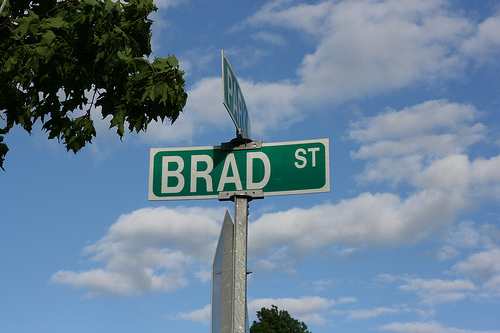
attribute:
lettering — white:
[160, 147, 319, 194]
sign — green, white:
[147, 138, 332, 200]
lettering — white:
[226, 66, 248, 134]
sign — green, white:
[221, 49, 253, 141]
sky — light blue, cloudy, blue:
[1, 1, 499, 331]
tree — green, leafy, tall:
[0, 1, 189, 171]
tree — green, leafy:
[249, 304, 310, 332]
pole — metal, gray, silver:
[229, 194, 253, 332]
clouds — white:
[17, 0, 499, 331]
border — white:
[148, 137, 332, 202]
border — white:
[220, 46, 248, 141]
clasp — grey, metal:
[216, 187, 265, 201]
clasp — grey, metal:
[222, 141, 264, 153]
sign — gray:
[211, 208, 235, 332]